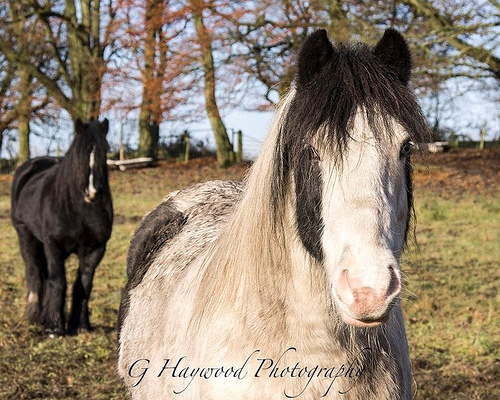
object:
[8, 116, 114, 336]
horses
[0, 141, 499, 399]
field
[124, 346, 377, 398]
watermark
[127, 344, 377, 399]
photographer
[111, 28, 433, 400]
horse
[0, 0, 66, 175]
trees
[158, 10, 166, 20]
leaves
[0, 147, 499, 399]
dry grass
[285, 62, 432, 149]
mane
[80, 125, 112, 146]
mane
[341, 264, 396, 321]
nose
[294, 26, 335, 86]
ear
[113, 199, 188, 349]
markings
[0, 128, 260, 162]
fence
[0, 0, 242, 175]
group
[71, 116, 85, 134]
ears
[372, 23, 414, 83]
ears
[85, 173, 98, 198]
markings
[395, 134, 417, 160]
eyes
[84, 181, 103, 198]
nose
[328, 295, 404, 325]
mouth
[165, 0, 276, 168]
tree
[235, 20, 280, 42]
branch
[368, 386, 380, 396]
bottom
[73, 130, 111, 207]
face